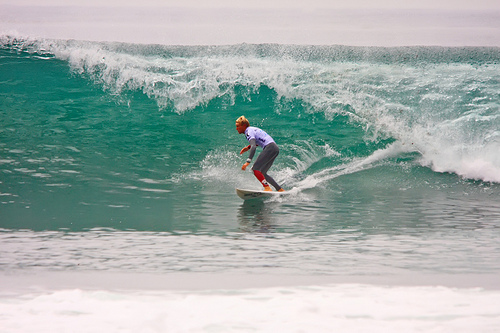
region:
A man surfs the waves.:
[231, 115, 302, 200]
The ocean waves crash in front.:
[16, 285, 483, 329]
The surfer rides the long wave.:
[9, 32, 488, 192]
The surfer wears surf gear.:
[233, 118, 289, 188]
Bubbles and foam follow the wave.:
[308, 52, 473, 167]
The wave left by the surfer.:
[301, 139, 393, 176]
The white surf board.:
[232, 185, 299, 200]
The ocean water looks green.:
[40, 173, 186, 230]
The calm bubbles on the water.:
[13, 223, 255, 275]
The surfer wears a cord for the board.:
[258, 177, 272, 189]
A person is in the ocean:
[25, 10, 456, 330]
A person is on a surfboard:
[11, 26, 481, 313]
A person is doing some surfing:
[22, 26, 475, 312]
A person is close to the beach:
[16, 18, 496, 324]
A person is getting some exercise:
[118, 51, 413, 302]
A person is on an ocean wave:
[25, 26, 486, 322]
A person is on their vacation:
[35, 21, 450, 316]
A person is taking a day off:
[20, 11, 466, 302]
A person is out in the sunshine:
[35, 30, 475, 310]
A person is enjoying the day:
[58, 27, 450, 316]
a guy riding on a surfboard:
[210, 103, 290, 205]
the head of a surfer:
[228, 101, 252, 136]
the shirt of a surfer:
[231, 122, 272, 146]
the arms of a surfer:
[227, 139, 268, 161]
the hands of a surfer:
[237, 136, 248, 166]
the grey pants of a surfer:
[250, 138, 288, 190]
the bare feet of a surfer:
[250, 175, 290, 190]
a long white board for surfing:
[222, 172, 284, 200]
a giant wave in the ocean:
[84, 59, 196, 147]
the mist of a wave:
[212, 136, 249, 191]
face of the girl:
[214, 99, 262, 139]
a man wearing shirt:
[236, 117, 279, 160]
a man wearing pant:
[260, 150, 295, 181]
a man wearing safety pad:
[237, 174, 277, 192]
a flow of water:
[215, 59, 485, 136]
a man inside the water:
[181, 83, 352, 238]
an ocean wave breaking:
[51, 24, 476, 138]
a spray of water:
[202, 148, 238, 179]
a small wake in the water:
[294, 143, 379, 183]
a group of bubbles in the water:
[277, 265, 497, 315]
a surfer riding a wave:
[221, 111, 303, 205]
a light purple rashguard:
[241, 120, 278, 147]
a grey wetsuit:
[236, 135, 288, 192]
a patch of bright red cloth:
[252, 168, 269, 189]